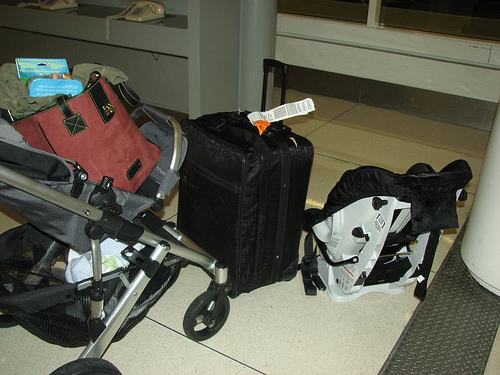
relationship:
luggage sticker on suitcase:
[246, 96, 317, 128] [173, 107, 317, 303]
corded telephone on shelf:
[104, 1, 168, 42] [0, 0, 196, 63]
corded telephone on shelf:
[13, 0, 83, 13] [0, 0, 196, 63]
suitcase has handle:
[173, 107, 317, 303] [261, 56, 292, 133]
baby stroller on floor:
[0, 57, 232, 373] [0, 83, 492, 374]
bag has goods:
[9, 71, 163, 197] [0, 57, 129, 121]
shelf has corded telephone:
[0, 0, 196, 63] [104, 1, 168, 42]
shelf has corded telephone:
[0, 0, 196, 63] [13, 0, 83, 13]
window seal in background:
[272, 9, 499, 52] [257, 0, 499, 133]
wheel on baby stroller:
[182, 288, 230, 345] [0, 57, 232, 373]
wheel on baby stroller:
[42, 356, 130, 374] [0, 57, 232, 373]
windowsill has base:
[271, 9, 499, 68] [269, 31, 499, 106]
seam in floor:
[267, 100, 499, 154] [0, 83, 492, 374]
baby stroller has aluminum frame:
[0, 57, 232, 373] [1, 105, 231, 358]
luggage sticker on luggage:
[246, 96, 317, 128] [173, 107, 317, 303]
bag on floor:
[9, 71, 163, 197] [0, 83, 492, 374]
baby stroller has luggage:
[0, 57, 232, 373] [9, 71, 163, 197]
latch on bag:
[102, 103, 118, 119] [9, 71, 163, 197]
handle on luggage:
[261, 56, 292, 133] [173, 107, 317, 303]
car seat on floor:
[299, 157, 473, 310] [0, 83, 492, 374]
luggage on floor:
[173, 107, 317, 303] [0, 83, 492, 374]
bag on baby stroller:
[9, 71, 163, 197] [0, 57, 232, 373]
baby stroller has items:
[0, 57, 232, 373] [0, 57, 129, 121]